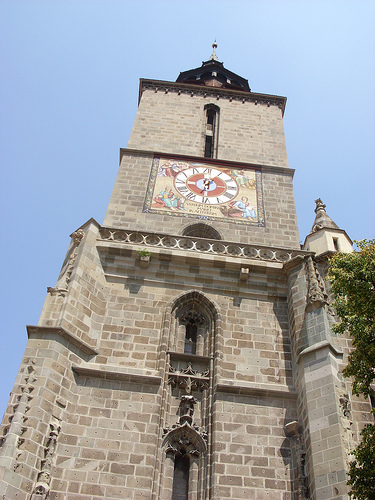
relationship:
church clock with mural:
[170, 161, 241, 205] [141, 150, 269, 229]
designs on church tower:
[143, 288, 224, 498] [0, 35, 373, 498]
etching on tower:
[1, 359, 60, 498] [62, 35, 373, 481]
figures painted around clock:
[148, 156, 257, 220] [173, 161, 241, 206]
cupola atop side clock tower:
[300, 197, 353, 254] [0, 36, 375, 500]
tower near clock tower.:
[302, 198, 354, 255] [102, 38, 300, 244]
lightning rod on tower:
[201, 37, 224, 68] [101, 64, 301, 250]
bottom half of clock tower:
[2, 216, 374, 498] [0, 36, 375, 497]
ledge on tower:
[77, 213, 313, 281] [0, 38, 373, 497]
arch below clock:
[166, 220, 232, 239] [173, 161, 241, 206]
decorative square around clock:
[143, 152, 268, 228] [173, 161, 241, 206]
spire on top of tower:
[199, 33, 224, 67] [0, 38, 373, 497]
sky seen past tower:
[0, 1, 373, 425] [0, 38, 373, 497]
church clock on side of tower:
[173, 164, 240, 206] [0, 38, 373, 497]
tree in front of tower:
[323, 237, 374, 398] [289, 198, 373, 498]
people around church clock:
[156, 155, 182, 174] [173, 164, 240, 206]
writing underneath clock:
[181, 200, 223, 219] [149, 155, 263, 216]